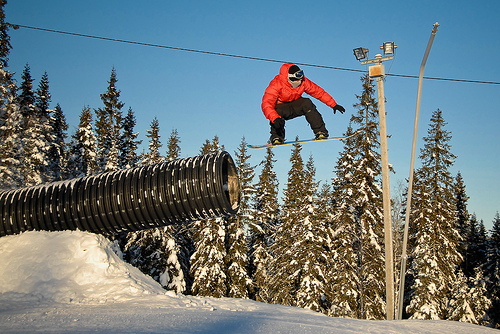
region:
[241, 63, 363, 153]
snowboard high in the air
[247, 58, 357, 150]
man in the air on a snowboard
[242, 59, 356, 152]
man and his snowboard in the air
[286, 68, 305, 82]
goggles on a snowboarder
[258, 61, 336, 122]
red coat on a snowboarder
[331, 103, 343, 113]
black glove on a person's hand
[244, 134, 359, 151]
snowboard in the air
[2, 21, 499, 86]
black wire in the air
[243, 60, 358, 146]
person on a board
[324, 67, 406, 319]
tall pine tree covered with snow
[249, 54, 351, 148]
snow boarder iwth red jacket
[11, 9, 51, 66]
white clouds in blue sky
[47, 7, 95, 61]
white clouds in blue sky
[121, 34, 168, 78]
white clouds in blue sky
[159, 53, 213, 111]
white clouds in blue sky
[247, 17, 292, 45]
white clouds in blue sky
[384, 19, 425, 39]
white clouds in blue sky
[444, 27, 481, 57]
white clouds in blue sky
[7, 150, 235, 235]
A black tube covered in snow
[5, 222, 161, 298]
A snow pile holding up a black tube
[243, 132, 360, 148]
A snow board being ridden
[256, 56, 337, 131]
A red puffy winter jacket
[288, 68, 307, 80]
Goggles being worn by the man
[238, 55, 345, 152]
A man riding a snow board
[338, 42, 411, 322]
A light pole behind the man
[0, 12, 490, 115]
electricty wires running across the photo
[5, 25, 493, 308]
Snow covered pine trees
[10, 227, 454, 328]
The ground which is covered in snow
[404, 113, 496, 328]
A green tree covered with snow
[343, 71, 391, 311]
A green tree covered with snow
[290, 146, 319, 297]
A green tree covered with snow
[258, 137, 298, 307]
A green tree covered with snow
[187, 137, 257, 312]
A green tree covered with snow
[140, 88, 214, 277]
A green tree covered with snow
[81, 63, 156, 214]
A green tree covered with snow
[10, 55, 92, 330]
A green tree covered with snow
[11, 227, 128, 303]
A heap of white snow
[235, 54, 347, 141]
A man snow skating